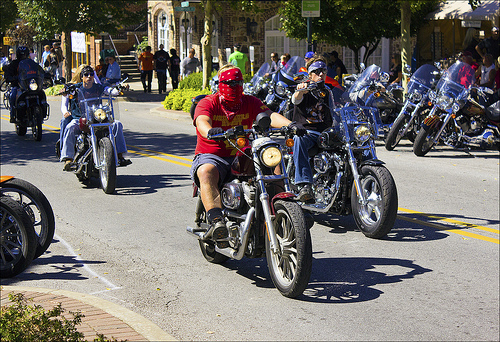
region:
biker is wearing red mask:
[185, 62, 317, 282]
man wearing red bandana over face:
[196, 56, 267, 112]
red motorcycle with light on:
[192, 145, 351, 301]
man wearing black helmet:
[68, 61, 106, 99]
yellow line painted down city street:
[402, 196, 499, 271]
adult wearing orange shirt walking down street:
[136, 43, 158, 98]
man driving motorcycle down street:
[288, 54, 407, 251]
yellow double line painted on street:
[132, 131, 199, 185]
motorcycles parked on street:
[385, 57, 498, 174]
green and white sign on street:
[293, 1, 333, 76]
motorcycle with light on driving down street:
[5, 44, 53, 139]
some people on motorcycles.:
[19, 21, 468, 327]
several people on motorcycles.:
[15, 31, 455, 321]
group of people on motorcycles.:
[12, 27, 437, 316]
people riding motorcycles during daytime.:
[30, 25, 465, 325]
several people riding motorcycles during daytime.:
[15, 20, 450, 314]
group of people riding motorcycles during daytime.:
[35, 10, 459, 333]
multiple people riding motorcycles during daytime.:
[9, 17, 457, 323]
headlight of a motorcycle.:
[255, 144, 292, 172]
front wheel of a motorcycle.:
[254, 191, 317, 307]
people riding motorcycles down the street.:
[45, 24, 445, 303]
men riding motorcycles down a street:
[3, 45, 405, 295]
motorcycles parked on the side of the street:
[282, 45, 497, 161]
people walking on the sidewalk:
[95, 40, 248, 102]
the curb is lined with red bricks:
[2, 280, 172, 340]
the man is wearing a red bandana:
[217, 65, 244, 105]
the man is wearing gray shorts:
[190, 146, 236, 241]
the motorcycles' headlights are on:
[15, 75, 377, 181]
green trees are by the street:
[8, 0, 498, 73]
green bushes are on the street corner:
[160, 70, 225, 115]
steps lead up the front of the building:
[98, 15, 192, 90]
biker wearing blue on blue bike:
[57, 61, 138, 204]